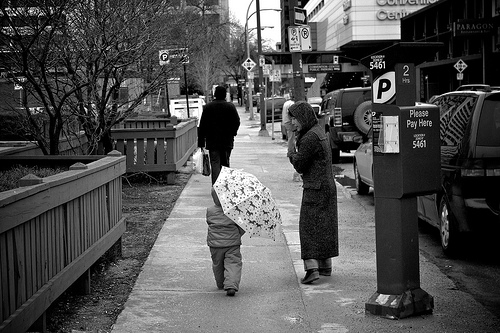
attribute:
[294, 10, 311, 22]
street sign — One way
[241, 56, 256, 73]
sign — directional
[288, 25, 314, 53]
sign — directional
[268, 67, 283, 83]
sign — directional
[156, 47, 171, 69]
sign — directional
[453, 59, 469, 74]
sign — directional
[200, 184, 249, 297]
child — small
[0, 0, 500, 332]
picture — black and white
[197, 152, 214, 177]
bag — white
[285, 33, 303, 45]
arrow — white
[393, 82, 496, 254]
suv — dark colored, parked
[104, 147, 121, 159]
post — three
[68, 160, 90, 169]
post — three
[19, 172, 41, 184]
post — three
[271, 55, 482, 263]
cars — parked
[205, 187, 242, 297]
child — small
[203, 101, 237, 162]
clothing — dark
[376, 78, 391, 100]
letter — black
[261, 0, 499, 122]
buildings — in the background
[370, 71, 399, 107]
sign — parking